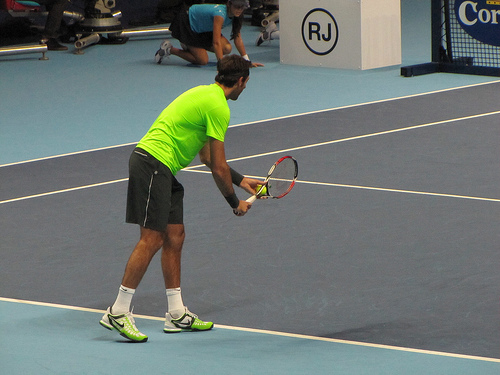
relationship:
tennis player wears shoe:
[101, 54, 267, 342] [99, 306, 148, 343]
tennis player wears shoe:
[101, 54, 267, 342] [164, 308, 214, 333]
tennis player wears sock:
[101, 54, 267, 342] [111, 284, 135, 314]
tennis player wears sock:
[101, 54, 267, 342] [165, 287, 183, 319]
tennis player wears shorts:
[101, 54, 267, 342] [124, 147, 184, 233]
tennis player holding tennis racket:
[101, 54, 267, 342] [233, 155, 300, 215]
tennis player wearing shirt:
[101, 54, 267, 342] [136, 83, 231, 177]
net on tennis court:
[401, 0, 499, 78] [1, 0, 500, 374]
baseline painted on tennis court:
[10, 80, 498, 168] [1, 0, 500, 374]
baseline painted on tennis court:
[1, 296, 499, 363] [1, 0, 500, 374]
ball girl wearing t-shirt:
[154, 0, 265, 68] [189, 4, 234, 34]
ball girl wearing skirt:
[154, 0, 265, 68] [168, 8, 223, 51]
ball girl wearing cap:
[154, 0, 265, 68] [228, 0, 251, 8]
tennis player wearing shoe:
[101, 54, 267, 342] [99, 306, 148, 343]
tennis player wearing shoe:
[101, 54, 267, 342] [164, 308, 214, 333]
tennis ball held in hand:
[255, 183, 269, 196] [242, 178, 269, 201]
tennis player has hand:
[101, 54, 267, 342] [242, 178, 269, 201]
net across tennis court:
[401, 0, 499, 78] [1, 0, 500, 374]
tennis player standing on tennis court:
[101, 54, 267, 342] [1, 0, 500, 374]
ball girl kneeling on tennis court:
[154, 0, 265, 68] [1, 0, 500, 374]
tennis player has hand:
[101, 54, 267, 342] [234, 201, 253, 217]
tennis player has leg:
[101, 54, 267, 342] [162, 183, 186, 320]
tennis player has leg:
[101, 54, 267, 342] [113, 181, 166, 315]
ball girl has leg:
[154, 0, 265, 68] [172, 46, 209, 66]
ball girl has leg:
[154, 0, 265, 68] [207, 34, 232, 56]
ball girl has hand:
[154, 0, 265, 68] [249, 61, 265, 69]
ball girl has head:
[154, 0, 265, 68] [229, 0, 247, 18]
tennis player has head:
[101, 54, 267, 342] [216, 53, 250, 102]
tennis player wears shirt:
[101, 54, 267, 342] [136, 83, 231, 177]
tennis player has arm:
[101, 54, 267, 342] [199, 142, 248, 189]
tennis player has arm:
[101, 54, 267, 342] [209, 110, 239, 208]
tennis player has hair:
[101, 54, 267, 342] [215, 54, 252, 89]